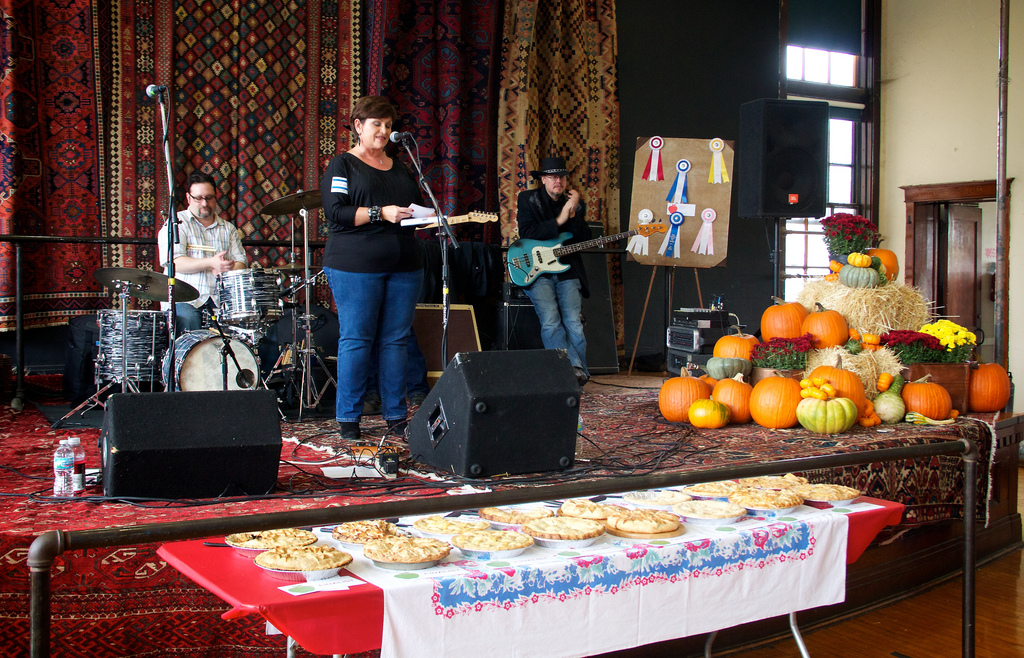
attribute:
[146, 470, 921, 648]
table — red, clothed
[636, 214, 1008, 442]
pumpkins — orange, numerous, small, big, green, sitting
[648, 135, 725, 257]
ribbons — displayed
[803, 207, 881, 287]
flowers — red, yellow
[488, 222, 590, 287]
guitar — teal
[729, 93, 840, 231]
speakers — black